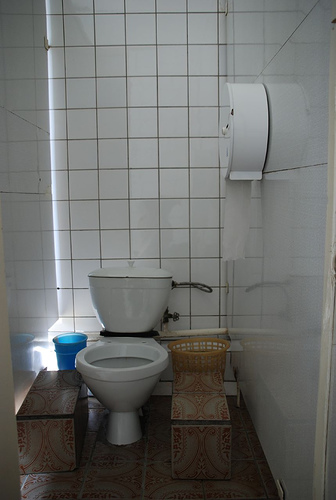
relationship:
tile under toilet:
[86, 392, 170, 482] [76, 271, 177, 447]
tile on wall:
[49, 1, 236, 395] [0, 14, 336, 499]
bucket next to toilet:
[55, 331, 87, 379] [76, 271, 177, 447]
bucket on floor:
[55, 331, 87, 379] [16, 380, 271, 500]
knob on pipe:
[172, 312, 181, 321] [161, 298, 188, 330]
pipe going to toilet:
[161, 298, 188, 330] [76, 271, 177, 447]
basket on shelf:
[162, 337, 230, 398] [173, 368, 238, 480]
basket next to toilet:
[162, 337, 230, 398] [76, 271, 177, 447]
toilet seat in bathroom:
[75, 330, 176, 389] [3, 2, 332, 499]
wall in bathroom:
[4, 4, 67, 411] [3, 2, 332, 499]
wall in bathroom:
[0, 14, 336, 499] [3, 2, 332, 499]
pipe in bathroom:
[161, 298, 188, 330] [3, 2, 332, 499]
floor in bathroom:
[16, 380, 271, 500] [3, 2, 332, 499]